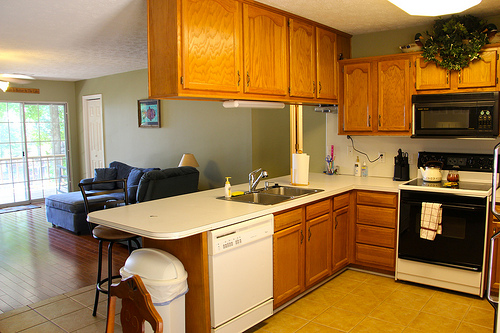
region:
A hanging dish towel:
[415, 193, 446, 244]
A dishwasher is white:
[200, 207, 275, 327]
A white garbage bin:
[115, 240, 190, 327]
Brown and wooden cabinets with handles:
[140, 0, 351, 110]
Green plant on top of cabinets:
[410, 10, 496, 75]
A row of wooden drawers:
[349, 182, 403, 282]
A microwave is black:
[405, 90, 495, 140]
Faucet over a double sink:
[211, 160, 322, 211]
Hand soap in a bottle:
[220, 170, 235, 200]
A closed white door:
[76, 90, 108, 181]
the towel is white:
[420, 207, 447, 241]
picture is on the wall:
[132, 100, 165, 128]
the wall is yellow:
[343, 270, 413, 331]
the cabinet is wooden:
[340, 63, 417, 128]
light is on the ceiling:
[391, 2, 488, 32]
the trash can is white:
[121, 249, 186, 324]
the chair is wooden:
[101, 271, 166, 326]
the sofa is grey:
[60, 145, 195, 240]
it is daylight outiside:
[11, 106, 62, 179]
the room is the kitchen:
[184, 28, 491, 332]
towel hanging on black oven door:
[409, 193, 456, 256]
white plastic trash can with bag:
[111, 241, 193, 331]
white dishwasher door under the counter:
[202, 207, 284, 332]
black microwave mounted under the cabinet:
[399, 85, 498, 162]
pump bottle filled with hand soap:
[217, 170, 239, 197]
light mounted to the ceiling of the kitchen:
[381, 0, 486, 21]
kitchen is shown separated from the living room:
[87, 9, 496, 323]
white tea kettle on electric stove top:
[414, 154, 443, 184]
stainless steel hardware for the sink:
[239, 165, 272, 190]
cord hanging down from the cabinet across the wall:
[340, 120, 388, 172]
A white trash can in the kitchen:
[111, 239, 218, 331]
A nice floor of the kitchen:
[320, 285, 445, 320]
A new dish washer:
[139, 187, 336, 330]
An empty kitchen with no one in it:
[302, 225, 448, 331]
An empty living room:
[60, 151, 186, 212]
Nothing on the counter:
[148, 184, 250, 226]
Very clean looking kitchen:
[226, 164, 479, 304]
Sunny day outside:
[21, 130, 74, 189]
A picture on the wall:
[126, 94, 177, 139]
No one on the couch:
[67, 168, 177, 213]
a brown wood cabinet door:
[178, 0, 240, 93]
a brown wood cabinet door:
[241, 0, 288, 95]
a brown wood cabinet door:
[288, 16, 315, 98]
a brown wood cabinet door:
[315, 26, 339, 101]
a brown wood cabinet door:
[341, 62, 374, 134]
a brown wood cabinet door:
[375, 58, 409, 132]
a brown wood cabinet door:
[413, 54, 451, 90]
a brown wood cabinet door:
[459, 49, 497, 89]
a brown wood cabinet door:
[331, 207, 351, 271]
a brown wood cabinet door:
[307, 213, 330, 286]